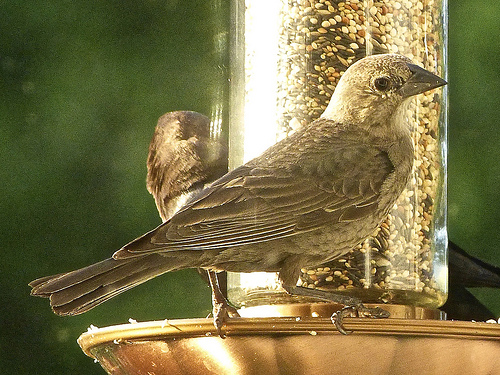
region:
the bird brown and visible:
[80, 30, 485, 275]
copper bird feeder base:
[78, 320, 499, 372]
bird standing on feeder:
[27, 53, 446, 326]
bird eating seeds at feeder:
[145, 108, 223, 220]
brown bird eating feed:
[31, 52, 443, 329]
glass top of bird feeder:
[227, 1, 450, 306]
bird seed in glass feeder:
[234, 0, 451, 305]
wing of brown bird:
[125, 118, 389, 243]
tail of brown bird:
[23, 249, 206, 315]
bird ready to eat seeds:
[26, 56, 446, 333]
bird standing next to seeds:
[35, 52, 440, 324]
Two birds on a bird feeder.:
[17, 20, 471, 346]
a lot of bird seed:
[210, 1, 465, 319]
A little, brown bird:
[20, 45, 446, 345]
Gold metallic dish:
[61, 316, 496, 368]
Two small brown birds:
[25, 55, 455, 338]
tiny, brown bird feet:
[176, 266, 397, 341]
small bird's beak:
[380, 46, 450, 106]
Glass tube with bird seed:
[225, 1, 450, 304]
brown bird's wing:
[91, 130, 411, 265]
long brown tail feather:
[17, 241, 201, 319]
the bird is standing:
[69, 94, 497, 294]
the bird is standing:
[107, 58, 407, 217]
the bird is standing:
[152, 26, 463, 264]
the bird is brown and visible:
[165, 102, 388, 319]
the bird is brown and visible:
[106, 27, 494, 311]